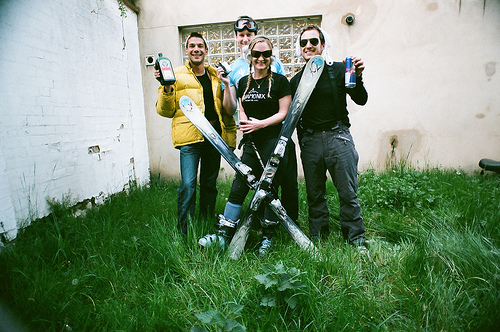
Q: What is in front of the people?
A: Two skis.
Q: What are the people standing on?
A: Tall grass.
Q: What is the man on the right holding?
A: A can of Red Bull.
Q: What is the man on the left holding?
A: A bottle of liquor.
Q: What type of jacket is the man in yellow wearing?
A: A ski jacket.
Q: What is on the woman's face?
A: Sunglasses.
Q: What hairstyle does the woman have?
A: Braids.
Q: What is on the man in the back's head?
A: Goggles.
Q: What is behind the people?
A: A wall with a large window.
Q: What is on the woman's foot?
A: A ski boot.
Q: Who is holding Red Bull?
A: Man on right.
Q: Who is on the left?
A: Man in yellow jacket.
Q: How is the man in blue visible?
A: Standing between people in front.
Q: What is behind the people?
A: Window.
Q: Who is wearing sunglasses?
A: Man on right and the woman.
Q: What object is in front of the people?
A: Skis.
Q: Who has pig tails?
A: Woman in middle.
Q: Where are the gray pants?
A: On man on right.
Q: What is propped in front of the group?
A: Set of skis.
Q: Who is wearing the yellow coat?
A: The man on the left.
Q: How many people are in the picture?
A: 4.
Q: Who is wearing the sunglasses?
A: The woman.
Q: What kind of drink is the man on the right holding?
A: Red Bull.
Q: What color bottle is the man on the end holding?
A: Green.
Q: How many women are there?
A: 1.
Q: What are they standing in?
A: Tall grass.